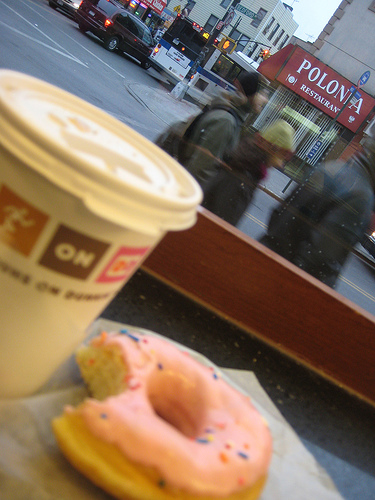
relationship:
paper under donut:
[8, 427, 55, 475] [70, 324, 295, 499]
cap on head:
[251, 114, 309, 163] [247, 113, 296, 176]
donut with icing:
[54, 328, 273, 499] [88, 325, 272, 493]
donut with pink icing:
[54, 328, 273, 499] [84, 329, 272, 493]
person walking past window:
[151, 67, 271, 207] [0, 0, 373, 321]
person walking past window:
[202, 117, 298, 227] [0, 0, 373, 321]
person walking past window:
[256, 117, 373, 286] [0, 0, 373, 321]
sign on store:
[279, 45, 334, 138] [256, 1, 373, 178]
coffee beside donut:
[51, 328, 271, 498] [0, 66, 203, 397]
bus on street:
[149, 9, 263, 107] [2, 1, 373, 313]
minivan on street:
[73, 2, 158, 69] [2, 1, 373, 313]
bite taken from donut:
[52, 332, 134, 424] [51, 325, 274, 499]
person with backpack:
[150, 72, 271, 207] [154, 109, 197, 157]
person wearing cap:
[150, 72, 271, 207] [235, 68, 264, 98]